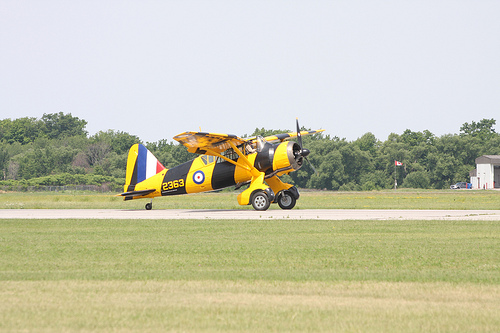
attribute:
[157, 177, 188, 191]
numbers — yellow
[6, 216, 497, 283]
grass — green, brown, dry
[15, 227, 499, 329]
grass — green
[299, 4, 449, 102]
clouds — white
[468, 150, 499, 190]
structure — large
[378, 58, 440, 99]
clouds — white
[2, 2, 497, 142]
sky — blue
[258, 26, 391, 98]
clouds — white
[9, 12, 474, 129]
sky — blue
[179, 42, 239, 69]
clouds — white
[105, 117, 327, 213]
plane — yellow, black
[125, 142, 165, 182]
stripe tail — red, white, blue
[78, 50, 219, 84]
clouds — white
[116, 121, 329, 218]
plane — black, yellow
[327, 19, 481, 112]
clouds — white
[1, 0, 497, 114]
sky — blue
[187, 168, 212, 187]
target — red, white, blue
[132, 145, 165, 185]
stripes — red, white, blue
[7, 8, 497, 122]
sky — blue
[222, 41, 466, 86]
clouds — white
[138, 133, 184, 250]
stripe — black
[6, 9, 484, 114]
sky — blue